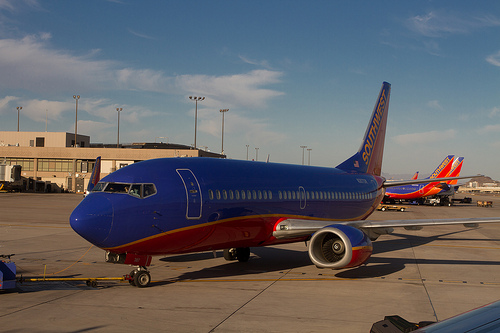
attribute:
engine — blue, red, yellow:
[306, 221, 374, 271]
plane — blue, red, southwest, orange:
[67, 80, 498, 290]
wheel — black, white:
[132, 269, 152, 289]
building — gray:
[0, 144, 229, 194]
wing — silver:
[270, 214, 500, 240]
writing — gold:
[361, 87, 390, 167]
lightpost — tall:
[185, 92, 209, 146]